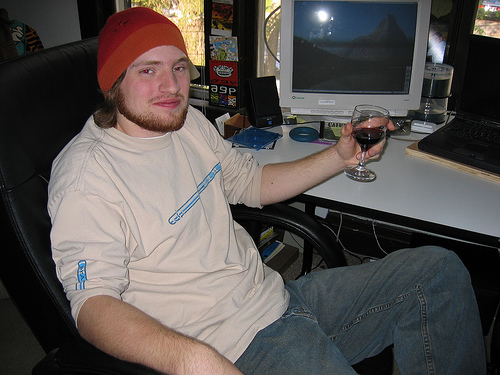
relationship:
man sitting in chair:
[48, 7, 490, 375] [1, 33, 393, 375]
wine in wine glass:
[352, 128, 385, 145] [342, 105, 390, 181]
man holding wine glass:
[48, 7, 490, 375] [342, 105, 390, 181]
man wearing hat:
[48, 7, 490, 375] [95, 5, 189, 100]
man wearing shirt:
[48, 7, 490, 375] [46, 104, 291, 363]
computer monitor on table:
[279, 2, 430, 125] [226, 109, 500, 282]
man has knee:
[48, 7, 490, 375] [402, 244, 472, 304]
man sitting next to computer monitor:
[48, 7, 490, 375] [279, 2, 430, 125]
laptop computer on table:
[417, 33, 499, 177] [226, 109, 500, 282]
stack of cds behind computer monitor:
[413, 61, 454, 125] [279, 2, 430, 125]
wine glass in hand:
[342, 105, 390, 181] [336, 116, 397, 166]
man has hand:
[48, 7, 490, 375] [336, 116, 397, 166]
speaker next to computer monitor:
[237, 75, 283, 130] [279, 2, 430, 125]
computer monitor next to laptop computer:
[279, 2, 430, 125] [417, 33, 499, 177]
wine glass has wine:
[342, 105, 390, 181] [352, 128, 385, 145]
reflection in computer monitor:
[312, 7, 336, 39] [279, 2, 430, 125]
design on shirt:
[164, 161, 224, 224] [46, 104, 291, 363]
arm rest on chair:
[231, 203, 348, 267] [1, 33, 393, 375]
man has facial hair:
[48, 7, 490, 375] [116, 88, 188, 134]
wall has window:
[91, 2, 499, 137] [129, 2, 210, 90]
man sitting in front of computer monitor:
[48, 7, 490, 375] [279, 2, 430, 125]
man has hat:
[48, 7, 490, 375] [95, 5, 189, 100]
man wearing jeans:
[48, 7, 490, 375] [232, 244, 487, 375]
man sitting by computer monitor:
[48, 7, 490, 375] [279, 2, 430, 125]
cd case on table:
[227, 125, 283, 149] [226, 109, 500, 282]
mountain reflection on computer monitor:
[337, 10, 407, 46] [279, 2, 430, 125]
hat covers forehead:
[95, 5, 189, 100] [127, 24, 188, 60]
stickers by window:
[208, 1, 240, 109] [129, 2, 210, 90]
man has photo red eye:
[48, 7, 490, 375] [143, 65, 180, 73]